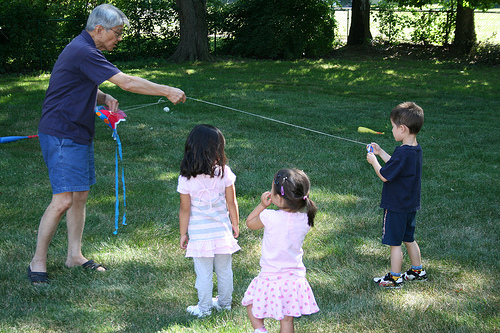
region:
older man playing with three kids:
[26, 5, 444, 313]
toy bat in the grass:
[351, 115, 386, 135]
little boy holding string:
[345, 101, 435, 286]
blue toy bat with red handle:
[0, 120, 35, 147]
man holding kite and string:
[30, 5, 185, 197]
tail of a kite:
[104, 138, 131, 230]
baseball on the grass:
[160, 100, 170, 110]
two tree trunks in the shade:
[336, 0, 481, 55]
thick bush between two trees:
[175, 0, 370, 55]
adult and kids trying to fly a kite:
[30, 5, 435, 312]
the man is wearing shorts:
[33, 124, 105, 196]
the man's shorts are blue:
[27, 125, 98, 198]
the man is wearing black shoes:
[24, 247, 106, 289]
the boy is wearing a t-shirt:
[374, 143, 429, 219]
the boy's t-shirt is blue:
[374, 138, 429, 218]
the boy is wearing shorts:
[372, 203, 423, 250]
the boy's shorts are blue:
[381, 197, 425, 252]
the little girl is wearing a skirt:
[227, 262, 328, 332]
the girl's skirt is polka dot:
[228, 274, 328, 331]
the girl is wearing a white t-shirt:
[248, 205, 312, 282]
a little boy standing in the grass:
[364, 98, 429, 288]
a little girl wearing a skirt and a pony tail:
[242, 165, 319, 332]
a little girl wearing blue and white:
[175, 120, 240, 315]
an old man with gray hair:
[26, 2, 184, 288]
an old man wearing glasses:
[25, 4, 188, 284]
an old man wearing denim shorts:
[25, 4, 186, 286]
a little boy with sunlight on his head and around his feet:
[352, 100, 492, 313]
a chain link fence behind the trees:
[321, 5, 499, 55]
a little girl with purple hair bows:
[239, 165, 322, 330]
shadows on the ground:
[2, 66, 498, 121]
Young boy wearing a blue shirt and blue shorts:
[370, 90, 427, 287]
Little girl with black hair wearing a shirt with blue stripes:
[167, 121, 244, 306]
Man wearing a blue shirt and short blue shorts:
[57, 5, 134, 247]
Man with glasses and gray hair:
[77, 5, 125, 50]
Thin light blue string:
[187, 93, 369, 167]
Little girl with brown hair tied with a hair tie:
[269, 169, 318, 239]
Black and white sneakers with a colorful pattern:
[365, 260, 437, 292]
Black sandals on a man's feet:
[17, 251, 112, 288]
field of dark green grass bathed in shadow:
[239, 65, 381, 110]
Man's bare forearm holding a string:
[116, 69, 194, 109]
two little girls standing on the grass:
[173, 123, 354, 332]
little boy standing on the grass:
[359, 94, 454, 296]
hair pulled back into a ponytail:
[304, 195, 321, 224]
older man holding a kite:
[19, 3, 155, 288]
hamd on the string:
[161, 81, 193, 113]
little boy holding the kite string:
[354, 93, 443, 288]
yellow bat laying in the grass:
[353, 122, 390, 142]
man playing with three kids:
[28, 3, 479, 329]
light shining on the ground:
[185, 66, 195, 76]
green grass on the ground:
[1, 65, 499, 332]